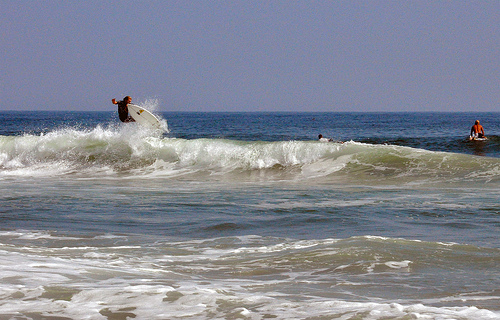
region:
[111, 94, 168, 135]
A surfer jumping from a wave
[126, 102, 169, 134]
A white surfboard in midair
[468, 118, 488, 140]
A man riding his surfboard in the ocean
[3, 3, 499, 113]
Grayish sky without clouds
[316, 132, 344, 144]
A man swimming on a surfboard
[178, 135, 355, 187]
A wave curling onto itself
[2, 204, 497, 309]
Bubbles forming on the water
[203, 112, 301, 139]
Blue water in the distance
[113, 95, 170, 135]
A man riding a white surfboard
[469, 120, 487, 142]
A man sitting on his surfboard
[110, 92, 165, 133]
a person surfing in the ocean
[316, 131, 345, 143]
a person surfing in the ocean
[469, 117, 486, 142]
a person surfing in the ocean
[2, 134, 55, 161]
white capped wave in ocean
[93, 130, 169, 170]
white capped wave in ocean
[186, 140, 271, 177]
white capped wave in ocean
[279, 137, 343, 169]
white capped wave in ocean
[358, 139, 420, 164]
white capped wave in ocean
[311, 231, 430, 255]
white capped wave in ocean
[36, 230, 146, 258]
white capped wave in ocean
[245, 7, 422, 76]
this is the sky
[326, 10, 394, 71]
the sky is blue in color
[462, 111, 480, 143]
this is a man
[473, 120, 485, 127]
the man is light skinned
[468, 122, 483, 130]
the man is bare chested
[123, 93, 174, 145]
this is a surfboard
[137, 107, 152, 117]
the board is white in color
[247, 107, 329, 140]
this is a water body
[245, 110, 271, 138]
the water is calm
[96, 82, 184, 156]
the man is surfing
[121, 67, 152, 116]
the head of a man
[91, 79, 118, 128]
the hand of a man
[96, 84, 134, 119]
the arm of a man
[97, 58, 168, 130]
a man on a surfboard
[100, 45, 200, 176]
a man riding a wave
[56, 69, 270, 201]
a wave in the water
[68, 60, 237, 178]
a man in the ocean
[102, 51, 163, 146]
the body of a man